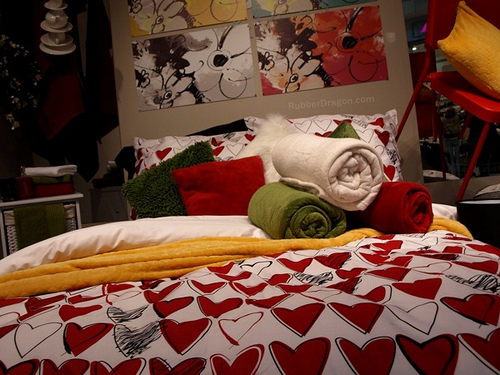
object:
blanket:
[271, 125, 379, 211]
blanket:
[249, 180, 347, 241]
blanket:
[374, 181, 435, 235]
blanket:
[8, 211, 500, 374]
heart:
[269, 303, 326, 337]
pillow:
[164, 155, 267, 215]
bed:
[4, 165, 498, 374]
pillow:
[121, 141, 216, 220]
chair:
[395, 3, 499, 197]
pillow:
[438, 5, 500, 97]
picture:
[126, 3, 390, 117]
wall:
[109, 2, 490, 220]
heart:
[216, 310, 266, 345]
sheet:
[431, 201, 459, 220]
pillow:
[131, 132, 259, 177]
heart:
[220, 139, 246, 156]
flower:
[192, 28, 258, 100]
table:
[0, 192, 86, 255]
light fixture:
[39, 2, 77, 56]